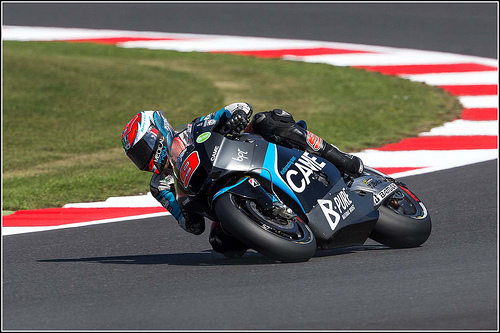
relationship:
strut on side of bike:
[376, 176, 433, 237] [164, 113, 434, 254]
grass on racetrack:
[26, 74, 135, 163] [66, 219, 466, 311]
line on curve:
[392, 55, 483, 95] [9, 10, 499, 225]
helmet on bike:
[122, 110, 174, 174] [166, 129, 443, 261]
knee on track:
[252, 111, 275, 136] [106, 238, 390, 313]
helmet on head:
[122, 115, 167, 153] [111, 104, 185, 174]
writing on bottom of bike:
[314, 200, 366, 220] [189, 132, 439, 254]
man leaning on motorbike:
[116, 101, 362, 257] [163, 107, 431, 261]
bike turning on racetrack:
[166, 129, 443, 261] [118, 260, 465, 309]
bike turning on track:
[166, 129, 443, 261] [192, 242, 328, 331]